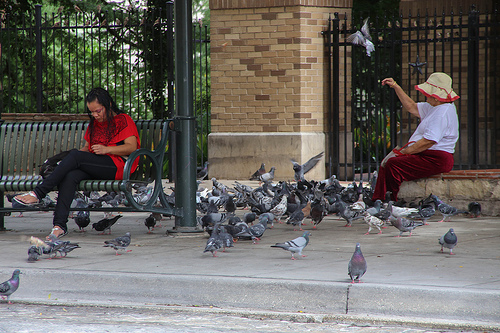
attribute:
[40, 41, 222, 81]
fence — iron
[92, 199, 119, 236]
bird — black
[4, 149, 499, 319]
birds — black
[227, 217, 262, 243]
bird — black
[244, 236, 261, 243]
spot — red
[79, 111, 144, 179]
shirt — red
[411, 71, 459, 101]
hat — tan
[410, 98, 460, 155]
shirt — white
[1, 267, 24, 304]
bird — Black 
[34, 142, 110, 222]
pants — black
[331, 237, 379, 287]
bird — grey, red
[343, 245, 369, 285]
bird — black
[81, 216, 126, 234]
bird — black